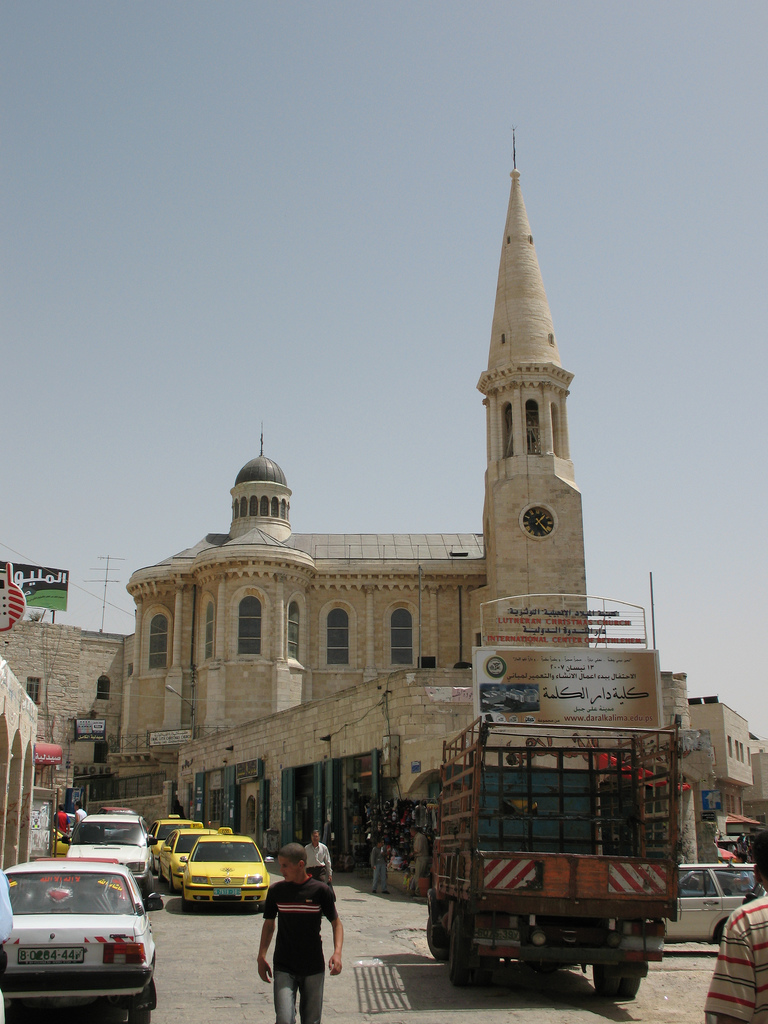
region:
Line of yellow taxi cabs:
[140, 803, 285, 941]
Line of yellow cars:
[136, 800, 273, 939]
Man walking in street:
[234, 817, 356, 1021]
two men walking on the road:
[255, 810, 370, 1020]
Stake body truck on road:
[407, 696, 703, 1017]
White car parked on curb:
[1, 844, 209, 1011]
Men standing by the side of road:
[352, 805, 455, 922]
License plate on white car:
[9, 934, 96, 978]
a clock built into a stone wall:
[497, 479, 583, 585]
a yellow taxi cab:
[189, 828, 271, 905]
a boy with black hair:
[277, 841, 314, 861]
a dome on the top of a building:
[230, 419, 290, 542]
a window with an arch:
[226, 588, 269, 664]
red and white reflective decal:
[484, 856, 537, 893]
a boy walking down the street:
[246, 838, 372, 1017]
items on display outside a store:
[339, 792, 430, 887]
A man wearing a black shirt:
[243, 829, 353, 996]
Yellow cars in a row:
[134, 797, 274, 924]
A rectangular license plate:
[3, 929, 97, 975]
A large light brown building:
[110, 108, 601, 882]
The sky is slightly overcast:
[3, 0, 760, 741]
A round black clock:
[510, 484, 564, 547]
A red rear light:
[91, 925, 154, 977]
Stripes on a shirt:
[687, 879, 759, 1015]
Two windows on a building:
[307, 590, 428, 683]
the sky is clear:
[241, 207, 335, 333]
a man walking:
[260, 848, 354, 1018]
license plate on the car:
[20, 944, 81, 971]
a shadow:
[353, 953, 418, 1019]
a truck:
[450, 725, 662, 913]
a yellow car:
[178, 828, 270, 908]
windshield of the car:
[9, 871, 117, 911]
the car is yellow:
[183, 828, 275, 915]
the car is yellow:
[166, 823, 190, 882]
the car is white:
[6, 853, 173, 1023]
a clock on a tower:
[514, 497, 563, 543]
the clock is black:
[514, 492, 563, 546]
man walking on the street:
[238, 834, 358, 1016]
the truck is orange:
[403, 698, 693, 1020]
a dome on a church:
[215, 407, 314, 571]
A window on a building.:
[392, 597, 419, 663]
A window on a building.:
[316, 603, 356, 663]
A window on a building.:
[282, 599, 301, 659]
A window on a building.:
[241, 593, 266, 658]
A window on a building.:
[151, 614, 168, 669]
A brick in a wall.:
[241, 678, 258, 693]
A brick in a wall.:
[307, 675, 325, 685]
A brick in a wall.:
[331, 676, 349, 685]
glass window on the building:
[236, 591, 262, 618]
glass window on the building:
[236, 612, 262, 628]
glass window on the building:
[233, 636, 262, 649]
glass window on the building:
[322, 605, 348, 624]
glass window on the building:
[321, 624, 346, 643]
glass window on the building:
[324, 645, 348, 663]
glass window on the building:
[389, 624, 408, 643]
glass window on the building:
[390, 646, 413, 664]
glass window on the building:
[145, 631, 168, 651]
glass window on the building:
[147, 652, 168, 667]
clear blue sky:
[145, 201, 241, 263]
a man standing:
[261, 851, 345, 1022]